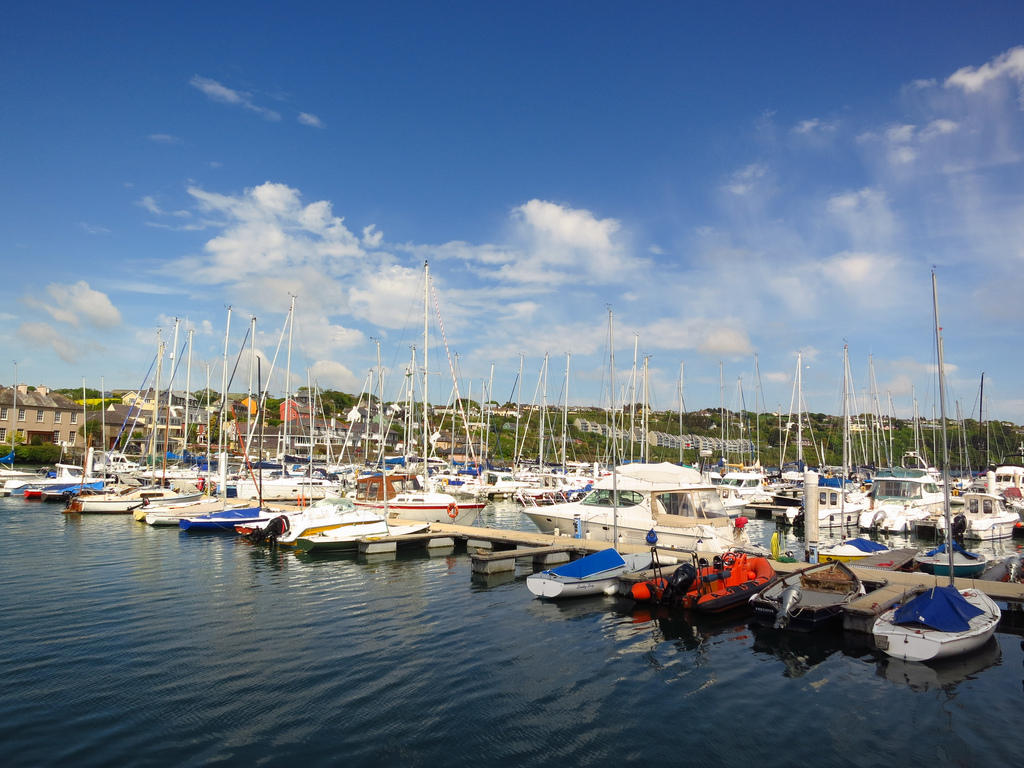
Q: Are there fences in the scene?
A: No, there are no fences.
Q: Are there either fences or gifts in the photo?
A: No, there are no fences or gifts.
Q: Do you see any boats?
A: Yes, there is a boat.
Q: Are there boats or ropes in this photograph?
A: Yes, there is a boat.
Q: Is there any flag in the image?
A: No, there are no flags.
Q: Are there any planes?
A: No, there are no planes.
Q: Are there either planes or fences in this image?
A: No, there are no planes or fences.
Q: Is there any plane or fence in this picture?
A: No, there are no airplanes or fences.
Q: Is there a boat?
A: Yes, there is a boat.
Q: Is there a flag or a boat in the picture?
A: Yes, there is a boat.